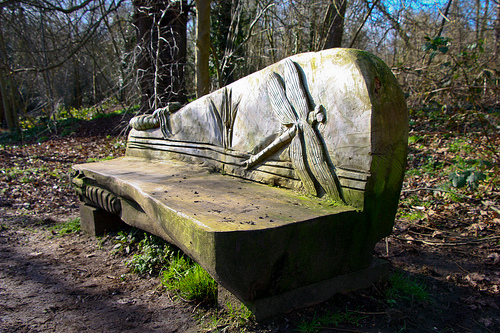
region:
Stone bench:
[50, 41, 442, 331]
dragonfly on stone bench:
[227, 50, 351, 206]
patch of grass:
[372, 270, 441, 310]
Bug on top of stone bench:
[121, 93, 187, 135]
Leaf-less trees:
[8, 0, 170, 112]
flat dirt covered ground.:
[1, 236, 137, 331]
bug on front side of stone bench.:
[56, 157, 135, 224]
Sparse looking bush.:
[404, 29, 499, 229]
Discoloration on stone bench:
[154, 199, 207, 261]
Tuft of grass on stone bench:
[191, 74, 249, 164]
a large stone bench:
[61, 45, 421, 298]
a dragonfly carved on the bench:
[235, 57, 352, 209]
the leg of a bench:
[213, 252, 397, 329]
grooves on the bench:
[129, 128, 366, 197]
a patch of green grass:
[154, 235, 224, 307]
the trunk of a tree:
[191, 0, 217, 97]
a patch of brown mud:
[0, 202, 200, 329]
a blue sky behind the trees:
[1, 0, 498, 55]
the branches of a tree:
[126, 0, 178, 115]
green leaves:
[443, 168, 467, 190]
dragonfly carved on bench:
[230, 50, 351, 211]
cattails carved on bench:
[196, 81, 248, 176]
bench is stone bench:
[58, 41, 419, 324]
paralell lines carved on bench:
[120, 126, 370, 196]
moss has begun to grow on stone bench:
[92, 36, 421, 248]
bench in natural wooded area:
[0, 0, 498, 332]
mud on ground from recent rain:
[1, 201, 255, 331]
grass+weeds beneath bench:
[101, 218, 236, 324]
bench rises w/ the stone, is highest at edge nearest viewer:
[116, 41, 413, 226]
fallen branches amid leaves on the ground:
[387, 163, 497, 278]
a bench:
[194, 120, 281, 330]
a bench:
[239, 159, 286, 323]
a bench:
[223, 211, 298, 316]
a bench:
[186, 155, 235, 248]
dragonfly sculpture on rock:
[260, 68, 377, 220]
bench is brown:
[70, 111, 351, 273]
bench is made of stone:
[59, 93, 296, 281]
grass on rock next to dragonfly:
[175, 89, 267, 151]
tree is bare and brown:
[14, 1, 164, 118]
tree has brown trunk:
[173, 16, 229, 89]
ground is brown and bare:
[1, 207, 155, 309]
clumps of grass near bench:
[112, 245, 226, 329]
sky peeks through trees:
[391, 3, 466, 46]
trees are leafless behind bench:
[381, 18, 495, 107]